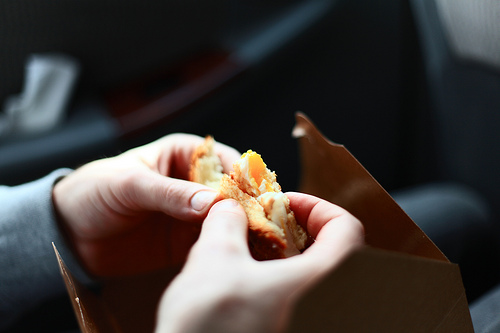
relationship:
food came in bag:
[183, 137, 303, 260] [51, 112, 474, 333]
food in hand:
[183, 137, 303, 252] [149, 194, 369, 324]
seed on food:
[267, 239, 286, 249] [183, 137, 303, 260]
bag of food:
[51, 112, 475, 332] [183, 137, 303, 252]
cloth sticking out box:
[4, 47, 81, 132] [0, 110, 120, 187]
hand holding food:
[59, 132, 365, 333] [183, 137, 303, 260]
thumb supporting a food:
[185, 191, 257, 271] [183, 137, 303, 260]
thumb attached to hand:
[185, 191, 257, 271] [52, 157, 161, 279]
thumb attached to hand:
[185, 191, 257, 271] [159, 252, 338, 331]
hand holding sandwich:
[59, 132, 194, 261] [164, 127, 329, 267]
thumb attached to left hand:
[119, 165, 224, 218] [52, 130, 244, 282]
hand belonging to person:
[59, 132, 365, 333] [2, 127, 497, 332]